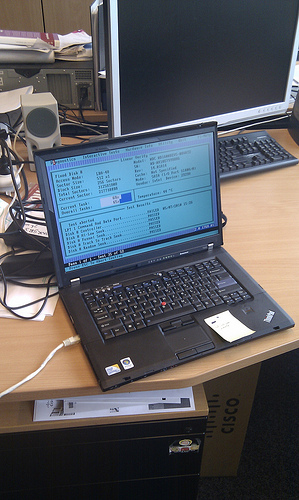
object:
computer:
[31, 119, 294, 394]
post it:
[202, 306, 257, 343]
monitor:
[117, 1, 297, 139]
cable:
[0, 332, 92, 399]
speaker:
[18, 90, 62, 172]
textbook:
[0, 30, 57, 55]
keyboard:
[78, 256, 251, 339]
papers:
[0, 84, 35, 115]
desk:
[0, 130, 297, 412]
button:
[176, 345, 198, 361]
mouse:
[163, 324, 215, 362]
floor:
[131, 456, 297, 498]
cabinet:
[73, 414, 207, 499]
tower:
[3, 53, 93, 115]